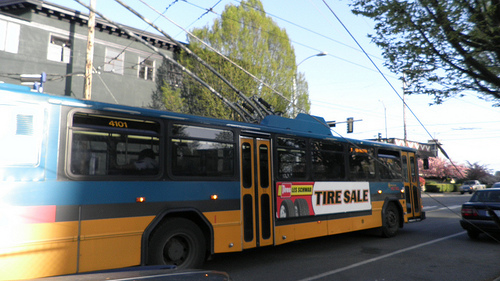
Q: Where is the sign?
A: On bus.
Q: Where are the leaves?
A: On tree.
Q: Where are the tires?
A: On bus.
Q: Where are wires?
A: Above bus.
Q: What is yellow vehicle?
A: Bus.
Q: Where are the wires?
A: Above bus.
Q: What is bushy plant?
A: Tree.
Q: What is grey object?
A: Building.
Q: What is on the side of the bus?
A: Doors.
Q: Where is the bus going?
A: Down the street.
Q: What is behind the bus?
A: A building.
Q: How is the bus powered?
A: With electrical wires.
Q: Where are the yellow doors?
A: On the bus.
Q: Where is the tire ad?
A: On the bus.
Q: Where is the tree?
A: Behind the bus.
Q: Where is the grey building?
A: Behind the bus.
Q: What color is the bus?
A: Yellow and blue.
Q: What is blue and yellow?
A: Bus.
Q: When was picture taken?
A: Daytime.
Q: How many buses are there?
A: One.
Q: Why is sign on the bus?
A: Advertisement.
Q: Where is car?
A: In front of the bus.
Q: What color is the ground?
A: Grey.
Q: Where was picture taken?
A: On a city street.